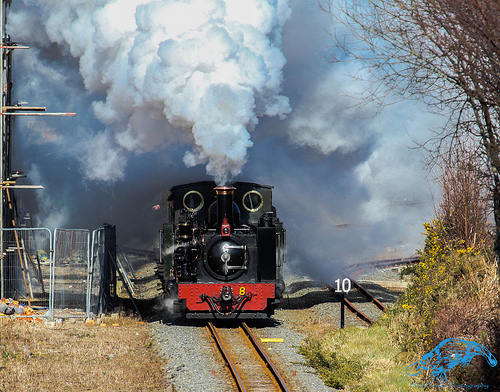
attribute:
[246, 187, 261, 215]
window — round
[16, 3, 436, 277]
sky — blue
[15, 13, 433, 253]
clouds — white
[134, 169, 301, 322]
train — black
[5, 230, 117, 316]
fence — chain link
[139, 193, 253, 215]
window — round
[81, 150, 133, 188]
clouds — white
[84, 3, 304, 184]
smoke — billowing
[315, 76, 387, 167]
clouds — white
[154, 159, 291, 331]
train — red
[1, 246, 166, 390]
grass — brown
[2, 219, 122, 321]
gate — metal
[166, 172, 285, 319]
train — black, red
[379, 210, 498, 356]
flowers — yellow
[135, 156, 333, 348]
train — black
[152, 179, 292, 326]
train — steam train, black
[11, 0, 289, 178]
smoke — white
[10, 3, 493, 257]
sky — blue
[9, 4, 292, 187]
cloud — white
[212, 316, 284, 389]
tracks — rusty, yellow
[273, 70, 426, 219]
clouds — white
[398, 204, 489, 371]
foliage — green, orange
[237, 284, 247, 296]
number — yellow 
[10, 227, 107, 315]
fence — silver, chain link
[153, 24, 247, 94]
clouds — white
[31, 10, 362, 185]
sky — grey, cloudy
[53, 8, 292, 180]
smoke — white, billowing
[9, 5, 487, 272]
steam — billowing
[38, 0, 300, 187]
smoke — white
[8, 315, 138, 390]
grass — dying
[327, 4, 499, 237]
tree — bare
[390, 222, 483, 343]
bush — green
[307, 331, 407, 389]
grass — green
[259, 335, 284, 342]
bar — Yellow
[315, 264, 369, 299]
number — white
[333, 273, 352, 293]
number — white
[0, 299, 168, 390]
grass — dry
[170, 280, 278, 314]
bumper — red